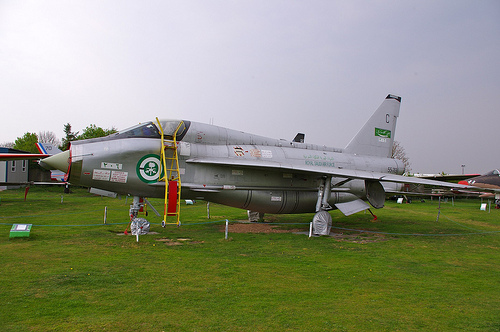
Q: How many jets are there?
A: One.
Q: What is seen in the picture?
A: Jet.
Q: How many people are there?
A: No one.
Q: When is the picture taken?
A: Daytime.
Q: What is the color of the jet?
A: Grey.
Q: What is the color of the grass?
A: Green.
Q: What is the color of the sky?
A: Blue.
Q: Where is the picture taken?
A: Museum.